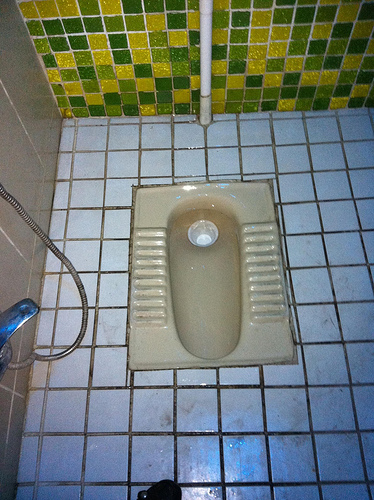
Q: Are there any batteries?
A: No, there are no batteries.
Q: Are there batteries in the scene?
A: No, there are no batteries.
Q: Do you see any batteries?
A: No, there are no batteries.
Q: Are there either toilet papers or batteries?
A: No, there are no batteries or toilet papers.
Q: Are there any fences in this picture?
A: No, there are no fences.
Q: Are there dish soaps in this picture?
A: No, there are no dish soaps.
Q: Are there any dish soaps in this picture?
A: No, there are no dish soaps.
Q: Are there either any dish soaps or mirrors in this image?
A: No, there are no dish soaps or mirrors.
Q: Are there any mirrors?
A: No, there are no mirrors.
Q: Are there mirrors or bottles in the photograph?
A: No, there are no mirrors or bottles.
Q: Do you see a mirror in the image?
A: No, there are no mirrors.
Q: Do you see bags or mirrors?
A: No, there are no mirrors or bags.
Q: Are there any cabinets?
A: No, there are no cabinets.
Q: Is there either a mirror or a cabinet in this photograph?
A: No, there are no cabinets or mirrors.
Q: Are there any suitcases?
A: No, there are no suitcases.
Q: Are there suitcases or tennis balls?
A: No, there are no suitcases or tennis balls.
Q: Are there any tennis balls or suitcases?
A: No, there are no suitcases or tennis balls.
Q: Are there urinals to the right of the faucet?
A: Yes, there is a urinal to the right of the faucet.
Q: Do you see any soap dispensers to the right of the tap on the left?
A: No, there is a urinal to the right of the faucet.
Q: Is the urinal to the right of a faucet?
A: Yes, the urinal is to the right of a faucet.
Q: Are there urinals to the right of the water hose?
A: Yes, there is a urinal to the right of the water hose.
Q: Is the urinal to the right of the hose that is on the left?
A: Yes, the urinal is to the right of the hose.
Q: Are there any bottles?
A: No, there are no bottles.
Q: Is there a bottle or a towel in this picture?
A: No, there are no bottles or towels.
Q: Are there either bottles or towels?
A: No, there are no bottles or towels.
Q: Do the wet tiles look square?
A: Yes, the tiles are square.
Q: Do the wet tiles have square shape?
A: Yes, the tiles are square.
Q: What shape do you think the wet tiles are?
A: The tiles are square.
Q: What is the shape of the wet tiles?
A: The tiles are square.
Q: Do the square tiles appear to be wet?
A: Yes, the tiles are wet.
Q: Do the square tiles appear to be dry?
A: No, the tiles are wet.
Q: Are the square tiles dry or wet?
A: The tiles are wet.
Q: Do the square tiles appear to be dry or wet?
A: The tiles are wet.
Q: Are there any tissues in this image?
A: No, there are no tissues.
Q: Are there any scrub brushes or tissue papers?
A: No, there are no tissue papers or scrub brushes.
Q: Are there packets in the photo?
A: No, there are no packets.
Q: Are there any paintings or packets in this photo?
A: No, there are no packets or paintings.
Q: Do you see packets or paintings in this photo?
A: No, there are no packets or paintings.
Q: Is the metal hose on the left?
A: Yes, the hose is on the left of the image.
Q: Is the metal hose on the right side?
A: No, the hose is on the left of the image.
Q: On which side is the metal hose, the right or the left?
A: The water hose is on the left of the image.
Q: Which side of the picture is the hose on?
A: The hose is on the left of the image.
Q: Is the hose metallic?
A: Yes, the hose is metallic.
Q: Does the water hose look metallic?
A: Yes, the water hose is metallic.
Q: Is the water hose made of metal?
A: Yes, the water hose is made of metal.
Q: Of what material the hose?
A: The hose is made of metal.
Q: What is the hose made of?
A: The hose is made of metal.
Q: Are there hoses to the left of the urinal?
A: Yes, there is a hose to the left of the urinal.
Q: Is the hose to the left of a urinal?
A: Yes, the hose is to the left of a urinal.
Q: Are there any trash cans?
A: No, there are no trash cans.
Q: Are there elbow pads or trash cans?
A: No, there are no trash cans or elbow pads.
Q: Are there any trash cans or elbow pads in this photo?
A: No, there are no trash cans or elbow pads.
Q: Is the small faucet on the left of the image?
A: Yes, the tap is on the left of the image.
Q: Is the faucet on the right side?
A: No, the faucet is on the left of the image.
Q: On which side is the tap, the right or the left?
A: The tap is on the left of the image.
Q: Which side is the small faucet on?
A: The tap is on the left of the image.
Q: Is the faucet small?
A: Yes, the faucet is small.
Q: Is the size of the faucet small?
A: Yes, the faucet is small.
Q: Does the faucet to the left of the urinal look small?
A: Yes, the tap is small.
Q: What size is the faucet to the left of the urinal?
A: The faucet is small.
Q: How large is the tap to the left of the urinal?
A: The faucet is small.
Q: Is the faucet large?
A: No, the faucet is small.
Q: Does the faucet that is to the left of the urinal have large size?
A: No, the faucet is small.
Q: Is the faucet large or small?
A: The faucet is small.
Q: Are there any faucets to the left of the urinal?
A: Yes, there is a faucet to the left of the urinal.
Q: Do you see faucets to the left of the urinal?
A: Yes, there is a faucet to the left of the urinal.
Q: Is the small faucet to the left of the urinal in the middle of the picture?
A: Yes, the faucet is to the left of the urinal.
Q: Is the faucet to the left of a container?
A: No, the faucet is to the left of the urinal.